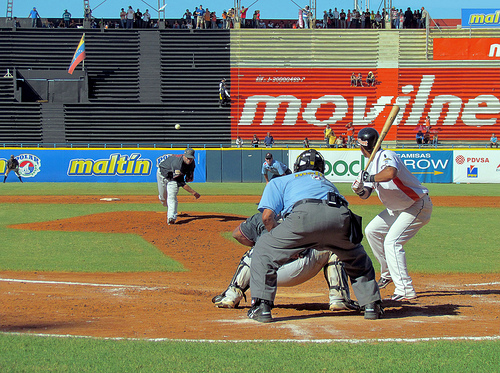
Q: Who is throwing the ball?
A: The pitcher.